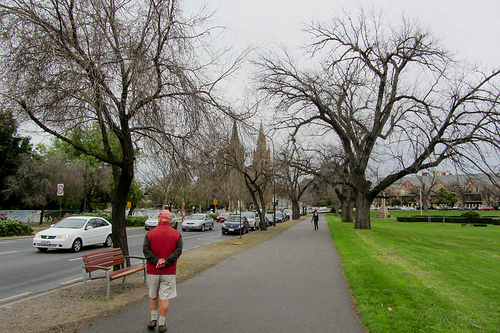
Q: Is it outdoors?
A: Yes, it is outdoors.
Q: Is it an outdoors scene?
A: Yes, it is outdoors.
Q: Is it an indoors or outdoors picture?
A: It is outdoors.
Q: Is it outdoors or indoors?
A: It is outdoors.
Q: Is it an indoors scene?
A: No, it is outdoors.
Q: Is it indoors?
A: No, it is outdoors.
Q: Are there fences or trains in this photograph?
A: No, there are no fences or trains.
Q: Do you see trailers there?
A: No, there are no trailers.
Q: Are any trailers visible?
A: No, there are no trailers.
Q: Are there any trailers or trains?
A: No, there are no trailers or trains.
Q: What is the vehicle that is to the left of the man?
A: The vehicle is a car.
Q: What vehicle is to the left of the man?
A: The vehicle is a car.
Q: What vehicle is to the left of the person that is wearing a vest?
A: The vehicle is a car.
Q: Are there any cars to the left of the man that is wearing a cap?
A: Yes, there is a car to the left of the man.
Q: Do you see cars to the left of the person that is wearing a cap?
A: Yes, there is a car to the left of the man.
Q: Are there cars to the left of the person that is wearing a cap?
A: Yes, there is a car to the left of the man.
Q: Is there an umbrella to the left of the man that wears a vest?
A: No, there is a car to the left of the man.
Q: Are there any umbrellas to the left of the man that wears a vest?
A: No, there is a car to the left of the man.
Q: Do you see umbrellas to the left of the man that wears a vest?
A: No, there is a car to the left of the man.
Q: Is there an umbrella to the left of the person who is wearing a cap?
A: No, there is a car to the left of the man.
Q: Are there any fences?
A: No, there are no fences.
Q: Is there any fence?
A: No, there are no fences.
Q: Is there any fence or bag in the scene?
A: No, there are no fences or bags.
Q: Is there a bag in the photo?
A: No, there are no bags.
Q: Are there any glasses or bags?
A: No, there are no bags or glasses.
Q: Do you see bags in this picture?
A: No, there are no bags.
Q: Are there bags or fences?
A: No, there are no bags or fences.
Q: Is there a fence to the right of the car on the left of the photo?
A: No, there is a person to the right of the car.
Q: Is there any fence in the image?
A: No, there are no fences.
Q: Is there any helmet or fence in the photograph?
A: No, there are no fences or helmets.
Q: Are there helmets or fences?
A: No, there are no fences or helmets.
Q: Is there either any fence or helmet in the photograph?
A: No, there are no fences or helmets.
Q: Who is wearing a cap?
A: The man is wearing a cap.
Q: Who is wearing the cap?
A: The man is wearing a cap.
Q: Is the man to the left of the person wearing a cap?
A: Yes, the man is wearing a cap.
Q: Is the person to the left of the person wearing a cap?
A: Yes, the man is wearing a cap.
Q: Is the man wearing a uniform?
A: No, the man is wearing a cap.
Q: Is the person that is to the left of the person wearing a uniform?
A: No, the man is wearing a cap.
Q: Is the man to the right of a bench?
A: Yes, the man is to the right of a bench.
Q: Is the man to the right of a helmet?
A: No, the man is to the right of a bench.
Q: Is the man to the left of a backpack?
A: No, the man is to the left of a car.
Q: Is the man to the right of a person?
A: No, the man is to the left of a person.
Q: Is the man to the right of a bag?
A: No, the man is to the right of a car.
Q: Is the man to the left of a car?
A: Yes, the man is to the left of a car.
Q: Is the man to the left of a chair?
A: No, the man is to the left of a car.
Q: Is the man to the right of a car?
A: No, the man is to the left of a car.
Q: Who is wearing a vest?
A: The man is wearing a vest.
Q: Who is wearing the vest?
A: The man is wearing a vest.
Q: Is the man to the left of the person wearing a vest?
A: Yes, the man is wearing a vest.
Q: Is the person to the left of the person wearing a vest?
A: Yes, the man is wearing a vest.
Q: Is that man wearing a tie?
A: No, the man is wearing a vest.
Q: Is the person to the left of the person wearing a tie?
A: No, the man is wearing a vest.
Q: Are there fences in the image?
A: No, there are no fences.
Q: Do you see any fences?
A: No, there are no fences.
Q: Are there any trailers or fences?
A: No, there are no fences or trailers.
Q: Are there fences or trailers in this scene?
A: No, there are no fences or trailers.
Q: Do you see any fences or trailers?
A: No, there are no fences or trailers.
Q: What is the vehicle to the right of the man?
A: The vehicle is a car.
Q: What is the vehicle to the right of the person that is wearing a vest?
A: The vehicle is a car.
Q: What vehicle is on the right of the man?
A: The vehicle is a car.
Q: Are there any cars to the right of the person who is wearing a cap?
A: Yes, there is a car to the right of the man.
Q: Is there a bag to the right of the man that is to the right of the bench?
A: No, there is a car to the right of the man.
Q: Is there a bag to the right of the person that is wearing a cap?
A: No, there is a car to the right of the man.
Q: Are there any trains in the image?
A: No, there are no trains.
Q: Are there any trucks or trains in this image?
A: No, there are no trains or trucks.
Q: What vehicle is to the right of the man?
A: The vehicle is a car.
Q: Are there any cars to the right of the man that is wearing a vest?
A: Yes, there is a car to the right of the man.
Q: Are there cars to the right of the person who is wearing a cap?
A: Yes, there is a car to the right of the man.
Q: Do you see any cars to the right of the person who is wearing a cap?
A: Yes, there is a car to the right of the man.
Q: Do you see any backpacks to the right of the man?
A: No, there is a car to the right of the man.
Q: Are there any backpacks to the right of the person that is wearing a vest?
A: No, there is a car to the right of the man.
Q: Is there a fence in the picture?
A: No, there are no fences.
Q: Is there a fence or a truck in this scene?
A: No, there are no fences or trucks.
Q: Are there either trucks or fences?
A: No, there are no fences or trucks.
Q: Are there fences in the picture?
A: No, there are no fences.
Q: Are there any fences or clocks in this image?
A: No, there are no fences or clocks.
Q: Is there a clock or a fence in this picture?
A: No, there are no fences or clocks.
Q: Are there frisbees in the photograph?
A: No, there are no frisbees.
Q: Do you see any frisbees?
A: No, there are no frisbees.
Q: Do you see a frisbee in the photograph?
A: No, there are no frisbees.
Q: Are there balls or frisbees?
A: No, there are no frisbees or balls.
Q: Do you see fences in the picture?
A: No, there are no fences.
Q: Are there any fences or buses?
A: No, there are no fences or buses.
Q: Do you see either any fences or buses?
A: No, there are no fences or buses.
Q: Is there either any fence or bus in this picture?
A: No, there are no fences or buses.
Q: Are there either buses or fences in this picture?
A: No, there are no fences or buses.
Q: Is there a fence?
A: No, there are no fences.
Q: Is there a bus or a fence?
A: No, there are no fences or buses.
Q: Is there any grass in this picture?
A: Yes, there is grass.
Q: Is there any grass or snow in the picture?
A: Yes, there is grass.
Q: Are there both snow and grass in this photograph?
A: No, there is grass but no snow.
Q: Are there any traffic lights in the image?
A: No, there are no traffic lights.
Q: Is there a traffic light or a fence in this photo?
A: No, there are no traffic lights or fences.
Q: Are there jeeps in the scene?
A: No, there are no jeeps.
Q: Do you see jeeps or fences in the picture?
A: No, there are no jeeps or fences.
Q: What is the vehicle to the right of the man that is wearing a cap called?
A: The vehicle is a car.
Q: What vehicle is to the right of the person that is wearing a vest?
A: The vehicle is a car.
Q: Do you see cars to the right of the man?
A: Yes, there is a car to the right of the man.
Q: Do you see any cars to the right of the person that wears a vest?
A: Yes, there is a car to the right of the man.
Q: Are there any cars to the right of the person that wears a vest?
A: Yes, there is a car to the right of the man.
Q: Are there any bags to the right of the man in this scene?
A: No, there is a car to the right of the man.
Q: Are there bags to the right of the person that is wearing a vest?
A: No, there is a car to the right of the man.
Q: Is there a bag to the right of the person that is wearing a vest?
A: No, there is a car to the right of the man.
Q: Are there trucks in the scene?
A: No, there are no trucks.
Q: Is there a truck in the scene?
A: No, there are no trucks.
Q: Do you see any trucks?
A: No, there are no trucks.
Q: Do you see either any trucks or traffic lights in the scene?
A: No, there are no trucks or traffic lights.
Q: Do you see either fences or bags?
A: No, there are no fences or bags.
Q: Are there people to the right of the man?
A: Yes, there is a person to the right of the man.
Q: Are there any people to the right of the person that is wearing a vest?
A: Yes, there is a person to the right of the man.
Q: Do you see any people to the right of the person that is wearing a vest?
A: Yes, there is a person to the right of the man.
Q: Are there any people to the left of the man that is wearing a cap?
A: No, the person is to the right of the man.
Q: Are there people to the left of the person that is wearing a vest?
A: No, the person is to the right of the man.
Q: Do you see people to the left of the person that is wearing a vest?
A: No, the person is to the right of the man.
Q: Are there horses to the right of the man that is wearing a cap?
A: No, there is a person to the right of the man.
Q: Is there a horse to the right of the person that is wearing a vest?
A: No, there is a person to the right of the man.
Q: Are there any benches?
A: Yes, there is a bench.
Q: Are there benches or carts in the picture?
A: Yes, there is a bench.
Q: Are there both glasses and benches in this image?
A: No, there is a bench but no glasses.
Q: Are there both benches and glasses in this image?
A: No, there is a bench but no glasses.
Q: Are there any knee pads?
A: No, there are no knee pads.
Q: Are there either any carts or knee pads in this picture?
A: No, there are no knee pads or carts.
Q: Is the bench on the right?
A: No, the bench is on the left of the image.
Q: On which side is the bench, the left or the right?
A: The bench is on the left of the image.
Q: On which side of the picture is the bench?
A: The bench is on the left of the image.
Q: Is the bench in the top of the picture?
A: No, the bench is in the bottom of the image.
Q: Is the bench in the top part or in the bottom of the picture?
A: The bench is in the bottom of the image.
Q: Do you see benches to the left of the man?
A: Yes, there is a bench to the left of the man.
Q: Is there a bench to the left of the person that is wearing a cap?
A: Yes, there is a bench to the left of the man.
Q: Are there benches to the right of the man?
A: No, the bench is to the left of the man.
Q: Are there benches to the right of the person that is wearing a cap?
A: No, the bench is to the left of the man.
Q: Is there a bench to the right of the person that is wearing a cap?
A: No, the bench is to the left of the man.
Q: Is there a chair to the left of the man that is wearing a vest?
A: No, there is a bench to the left of the man.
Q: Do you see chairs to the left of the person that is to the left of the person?
A: No, there is a bench to the left of the man.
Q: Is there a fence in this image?
A: No, there are no fences.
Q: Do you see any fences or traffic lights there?
A: No, there are no fences or traffic lights.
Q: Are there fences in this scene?
A: No, there are no fences.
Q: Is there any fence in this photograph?
A: No, there are no fences.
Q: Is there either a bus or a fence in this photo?
A: No, there are no fences or buses.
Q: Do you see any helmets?
A: No, there are no helmets.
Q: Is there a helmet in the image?
A: No, there are no helmets.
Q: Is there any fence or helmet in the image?
A: No, there are no helmets or fences.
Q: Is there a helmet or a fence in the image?
A: No, there are no helmets or fences.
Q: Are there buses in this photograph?
A: No, there are no buses.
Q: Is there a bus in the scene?
A: No, there are no buses.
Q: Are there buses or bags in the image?
A: No, there are no buses or bags.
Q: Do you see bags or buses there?
A: No, there are no buses or bags.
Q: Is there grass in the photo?
A: Yes, there is grass.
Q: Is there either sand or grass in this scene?
A: Yes, there is grass.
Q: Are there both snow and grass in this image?
A: No, there is grass but no snow.